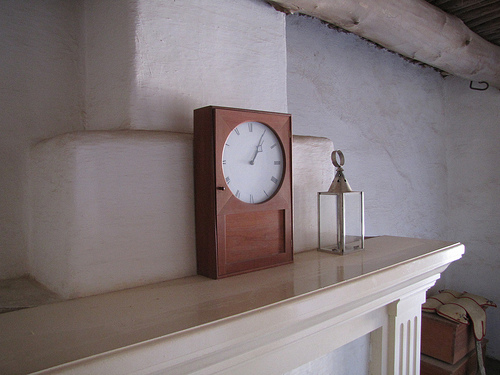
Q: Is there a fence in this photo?
A: No, there are no fences.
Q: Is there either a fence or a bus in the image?
A: No, there are no fences or buses.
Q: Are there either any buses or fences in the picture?
A: No, there are no fences or buses.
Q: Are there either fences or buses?
A: No, there are no fences or buses.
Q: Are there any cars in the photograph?
A: No, there are no cars.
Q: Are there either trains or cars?
A: No, there are no cars or trains.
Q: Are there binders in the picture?
A: No, there are no binders.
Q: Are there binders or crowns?
A: No, there are no binders or crowns.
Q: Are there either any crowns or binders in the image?
A: No, there are no binders or crowns.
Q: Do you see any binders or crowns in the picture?
A: No, there are no binders or crowns.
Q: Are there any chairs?
A: No, there are no chairs.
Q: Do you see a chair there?
A: No, there are no chairs.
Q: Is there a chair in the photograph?
A: No, there are no chairs.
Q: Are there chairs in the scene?
A: No, there are no chairs.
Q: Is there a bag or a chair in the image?
A: No, there are no chairs or bags.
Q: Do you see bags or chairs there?
A: No, there are no chairs or bags.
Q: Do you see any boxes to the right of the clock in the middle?
A: Yes, there is a box to the right of the clock.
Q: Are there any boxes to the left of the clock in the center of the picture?
A: No, the box is to the right of the clock.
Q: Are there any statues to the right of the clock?
A: No, there is a box to the right of the clock.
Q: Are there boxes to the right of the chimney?
A: Yes, there is a box to the right of the chimney.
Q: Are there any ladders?
A: No, there are no ladders.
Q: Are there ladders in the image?
A: No, there are no ladders.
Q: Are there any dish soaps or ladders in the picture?
A: No, there are no ladders or dish soaps.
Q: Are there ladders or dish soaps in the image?
A: No, there are no ladders or dish soaps.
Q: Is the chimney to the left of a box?
A: Yes, the chimney is to the left of a box.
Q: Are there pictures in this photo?
A: No, there are no pictures.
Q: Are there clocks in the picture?
A: Yes, there is a clock.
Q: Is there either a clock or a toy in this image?
A: Yes, there is a clock.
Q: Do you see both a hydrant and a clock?
A: No, there is a clock but no fire hydrants.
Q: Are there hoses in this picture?
A: No, there are no hoses.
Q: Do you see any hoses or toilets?
A: No, there are no hoses or toilets.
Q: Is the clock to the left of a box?
A: Yes, the clock is to the left of a box.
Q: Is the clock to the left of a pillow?
A: No, the clock is to the left of a box.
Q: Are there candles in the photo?
A: No, there are no candles.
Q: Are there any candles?
A: No, there are no candles.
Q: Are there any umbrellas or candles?
A: No, there are no candles or umbrellas.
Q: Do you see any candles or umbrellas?
A: No, there are no candles or umbrellas.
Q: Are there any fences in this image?
A: No, there are no fences.